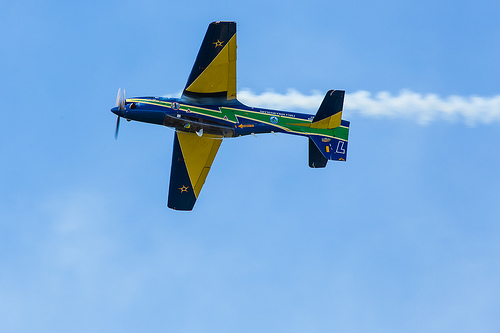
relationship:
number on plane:
[255, 85, 307, 121] [58, 37, 448, 222]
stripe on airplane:
[126, 95, 349, 142] [110, 20, 351, 210]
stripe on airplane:
[126, 85, 500, 141] [110, 20, 351, 210]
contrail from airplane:
[162, 87, 499, 129] [110, 20, 351, 210]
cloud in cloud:
[0, 0, 499, 333] [0, 0, 499, 333]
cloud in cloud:
[86, 256, 177, 315] [0, 0, 499, 333]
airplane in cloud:
[110, 20, 351, 210] [0, 0, 499, 333]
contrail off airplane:
[168, 91, 495, 121] [110, 20, 351, 210]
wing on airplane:
[167, 128, 223, 211] [110, 20, 351, 210]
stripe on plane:
[126, 85, 500, 141] [99, 13, 360, 224]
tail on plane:
[309, 89, 359, 134] [107, 10, 372, 213]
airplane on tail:
[110, 20, 351, 210] [309, 89, 359, 134]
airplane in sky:
[96, 18, 359, 215] [16, 9, 475, 314]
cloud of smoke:
[0, 0, 499, 333] [245, 88, 485, 118]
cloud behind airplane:
[0, 0, 499, 333] [110, 20, 351, 210]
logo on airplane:
[265, 110, 281, 129] [115, 21, 358, 211]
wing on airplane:
[168, 16, 242, 96] [110, 20, 351, 210]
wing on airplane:
[170, 125, 230, 211] [110, 20, 351, 210]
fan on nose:
[110, 87, 126, 140] [110, 87, 135, 141]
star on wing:
[213, 39, 223, 49] [184, 24, 240, 100]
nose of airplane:
[102, 90, 134, 128] [115, 21, 358, 211]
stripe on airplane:
[126, 85, 500, 141] [104, 8, 351, 224]